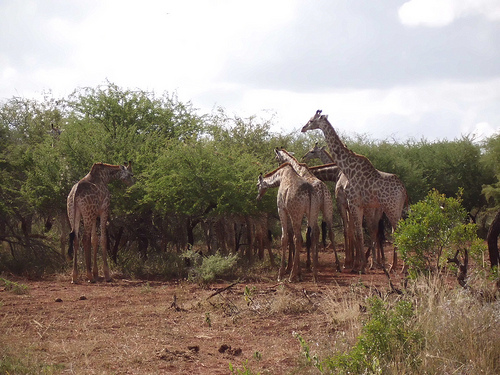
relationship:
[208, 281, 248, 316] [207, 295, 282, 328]
branches on ground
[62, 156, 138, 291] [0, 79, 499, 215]
giraffe eating leaves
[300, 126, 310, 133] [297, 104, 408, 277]
nose on giraffe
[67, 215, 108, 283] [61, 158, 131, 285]
legs on giraffe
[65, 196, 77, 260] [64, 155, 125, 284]
tail on giraffe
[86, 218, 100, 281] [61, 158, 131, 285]
leg on giraffe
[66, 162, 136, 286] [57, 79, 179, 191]
giraffe by tree